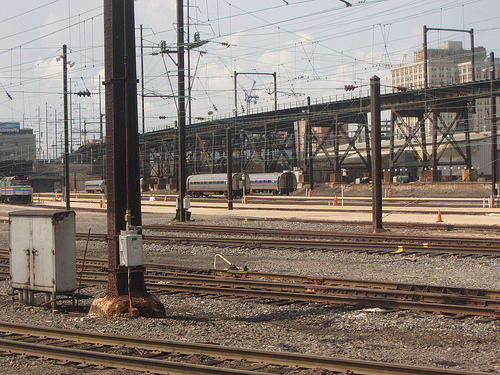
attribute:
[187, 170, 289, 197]
passenger car — silver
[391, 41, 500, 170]
building — large, white, tall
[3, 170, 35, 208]
train engine — silver blue, red, blue red, silver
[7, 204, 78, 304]
utility box — grey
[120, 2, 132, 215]
pole — rusty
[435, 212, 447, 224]
pylon — orange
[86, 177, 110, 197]
train — grey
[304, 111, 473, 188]
trestle supports — sway braces, sill